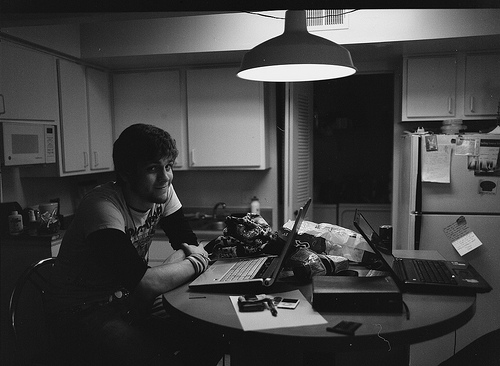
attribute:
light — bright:
[227, 22, 362, 89]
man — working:
[35, 118, 216, 359]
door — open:
[280, 78, 318, 227]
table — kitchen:
[154, 246, 482, 363]